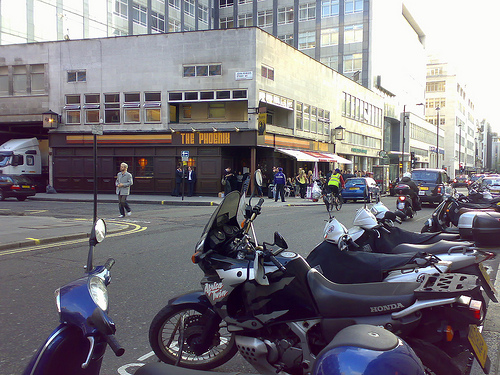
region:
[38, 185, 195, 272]
Curb on the road.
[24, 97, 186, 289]
Light post on the curb.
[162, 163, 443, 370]
Motorcycle on the road.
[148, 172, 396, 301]
Windshield on the road.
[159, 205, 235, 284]
Handle on the bike.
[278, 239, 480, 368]
Seat on the bike.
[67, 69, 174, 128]
Windows on the building.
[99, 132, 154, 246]
Person on the road.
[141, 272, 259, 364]
Wheel on the bike.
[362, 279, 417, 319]
brand on the bike.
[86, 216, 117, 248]
a side mirror on a street bike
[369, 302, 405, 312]
a "honda" logo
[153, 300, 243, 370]
a wheel on one of the bikes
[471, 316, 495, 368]
a license plate on one of the bikes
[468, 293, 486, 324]
a red reflector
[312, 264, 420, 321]
a black leather bike seat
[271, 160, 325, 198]
a group of people on the sidewalk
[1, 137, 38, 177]
the front of a semi truck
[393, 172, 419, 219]
a person riding a bike on the street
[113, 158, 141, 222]
a person crossing the street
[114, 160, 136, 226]
man walking in street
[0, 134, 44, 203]
a white truck in background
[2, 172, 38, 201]
black car parked on the street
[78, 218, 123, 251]
rearview mirror on blue bike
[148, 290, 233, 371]
front tire on motorcycle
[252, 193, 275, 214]
right handle bar on bike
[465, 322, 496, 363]
license plate on back of bike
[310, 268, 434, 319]
black seat on motorcycle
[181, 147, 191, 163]
blue and white sign on pole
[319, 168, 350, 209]
person riding bicycle in street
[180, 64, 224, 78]
row of windows on building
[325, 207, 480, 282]
row of motorcycles on street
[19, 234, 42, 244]
yellow line on side walk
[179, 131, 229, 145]
yellow letters on building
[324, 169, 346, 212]
person riding bicycle on street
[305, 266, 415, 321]
black seat on motorcylce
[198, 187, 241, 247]
windshield on black motorcycle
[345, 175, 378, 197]
small blue car on street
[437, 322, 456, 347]
tail light on motorcycle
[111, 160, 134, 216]
person walking across street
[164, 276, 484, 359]
that is a motorbike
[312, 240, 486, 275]
that is a motorbike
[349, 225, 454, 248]
that is a motorbike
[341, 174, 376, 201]
that is a car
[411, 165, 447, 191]
that is a car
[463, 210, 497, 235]
that is a car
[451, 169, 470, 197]
that is a car